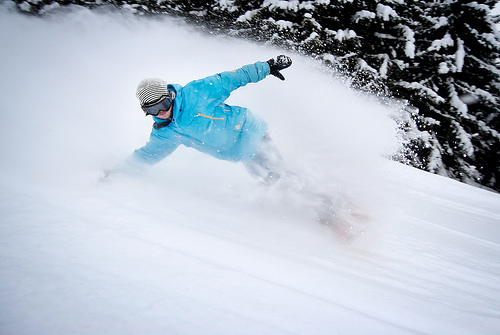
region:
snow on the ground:
[8, 43, 495, 323]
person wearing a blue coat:
[119, 52, 276, 172]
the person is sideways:
[33, 11, 491, 314]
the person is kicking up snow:
[8, 8, 436, 279]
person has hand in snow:
[60, 110, 177, 208]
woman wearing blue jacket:
[125, 44, 271, 199]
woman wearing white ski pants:
[246, 142, 326, 241]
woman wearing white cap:
[137, 78, 169, 103]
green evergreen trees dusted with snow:
[11, 2, 496, 181]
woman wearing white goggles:
[139, 93, 176, 117]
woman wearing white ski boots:
[311, 187, 367, 245]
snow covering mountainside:
[9, 9, 481, 327]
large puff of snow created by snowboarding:
[30, 29, 413, 219]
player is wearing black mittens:
[269, 58, 289, 83]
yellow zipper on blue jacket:
[195, 110, 245, 125]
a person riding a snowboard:
[52, 23, 387, 284]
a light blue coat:
[85, 38, 277, 185]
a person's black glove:
[258, 47, 310, 91]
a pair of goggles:
[131, 89, 172, 116]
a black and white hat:
[129, 70, 177, 107]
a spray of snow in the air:
[60, 10, 395, 180]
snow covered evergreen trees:
[41, 0, 497, 170]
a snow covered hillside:
[7, 123, 493, 331]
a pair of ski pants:
[252, 141, 337, 238]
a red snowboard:
[292, 142, 387, 271]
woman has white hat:
[124, 71, 190, 140]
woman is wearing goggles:
[143, 101, 200, 121]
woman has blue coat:
[133, 39, 313, 214]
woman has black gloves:
[236, 41, 323, 101]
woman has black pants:
[240, 105, 304, 209]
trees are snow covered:
[310, 0, 495, 181]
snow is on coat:
[143, 62, 268, 147]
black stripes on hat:
[133, 62, 185, 105]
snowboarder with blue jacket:
[120, 38, 325, 239]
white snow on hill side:
[43, 232, 94, 273]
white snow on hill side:
[216, 281, 270, 325]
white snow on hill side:
[95, 258, 149, 303]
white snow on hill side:
[210, 241, 254, 281]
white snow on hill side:
[47, 83, 79, 117]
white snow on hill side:
[93, 255, 141, 297]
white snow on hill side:
[197, 246, 228, 281]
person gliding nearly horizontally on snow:
[76, 49, 380, 245]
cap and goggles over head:
[135, 74, 171, 122]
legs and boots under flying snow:
[246, 130, 374, 243]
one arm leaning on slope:
[92, 82, 223, 208]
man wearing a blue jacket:
[143, 66, 253, 151]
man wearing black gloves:
[263, 50, 292, 80]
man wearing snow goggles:
[136, 95, 176, 120]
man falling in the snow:
[85, 44, 372, 249]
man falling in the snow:
[63, 38, 365, 235]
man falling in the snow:
[86, 50, 354, 240]